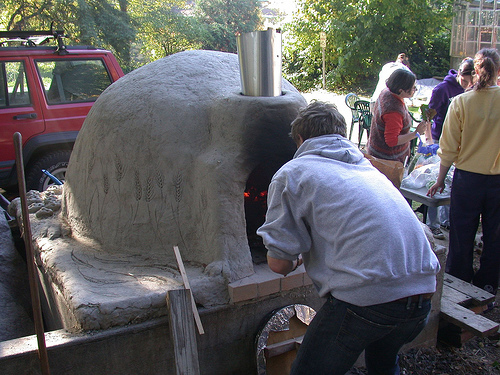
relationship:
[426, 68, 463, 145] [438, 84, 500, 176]
girl's hoodie purple jacket sweater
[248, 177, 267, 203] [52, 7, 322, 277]
coals inside oven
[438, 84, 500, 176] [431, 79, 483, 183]
sweater wearing sweater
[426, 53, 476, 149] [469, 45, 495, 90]
lady with ponytail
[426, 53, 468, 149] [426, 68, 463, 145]
lady wearing girl's hoodie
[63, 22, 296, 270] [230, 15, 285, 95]
clay oven has an exhaust pipe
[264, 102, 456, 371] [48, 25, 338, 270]
man in front of clay oven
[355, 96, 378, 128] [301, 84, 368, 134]
green chair on street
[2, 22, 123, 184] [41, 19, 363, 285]
car in front of clay oven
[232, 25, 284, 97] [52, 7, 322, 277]
exhaust pipe on top of oven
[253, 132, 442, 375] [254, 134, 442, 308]
man wearing wearing grey hoodie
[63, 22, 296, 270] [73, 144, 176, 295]
clay oven has designs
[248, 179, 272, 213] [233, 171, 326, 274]
coals glowing oven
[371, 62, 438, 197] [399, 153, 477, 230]
women at table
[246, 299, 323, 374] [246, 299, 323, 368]
object covering object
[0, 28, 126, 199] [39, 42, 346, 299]
car on oven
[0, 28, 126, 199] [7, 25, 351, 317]
car parked near clay oven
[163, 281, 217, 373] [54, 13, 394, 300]
two by four leaning stove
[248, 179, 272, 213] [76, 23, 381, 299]
coals burning in ovens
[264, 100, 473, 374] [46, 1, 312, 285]
person using using oven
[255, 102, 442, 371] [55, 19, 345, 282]
man forward in oven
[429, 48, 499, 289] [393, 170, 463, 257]
woman dressed touching table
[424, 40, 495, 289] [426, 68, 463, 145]
woman dressed in girl's hoodie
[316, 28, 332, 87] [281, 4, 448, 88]
sign in front in foliage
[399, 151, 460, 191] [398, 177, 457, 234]
packages on table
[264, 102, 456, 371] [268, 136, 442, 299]
man wearing jacket